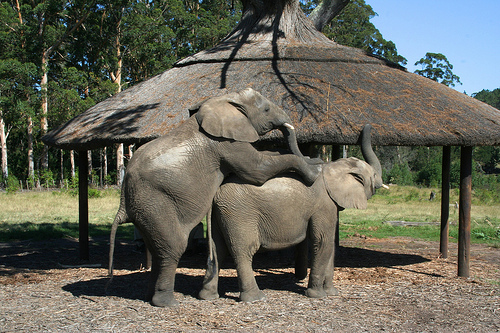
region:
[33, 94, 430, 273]
These are two elephants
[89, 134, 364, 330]
the elephants are large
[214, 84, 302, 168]
this is an ear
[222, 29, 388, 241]
this is a hut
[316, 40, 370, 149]
this is a roof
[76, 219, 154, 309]
this is a tail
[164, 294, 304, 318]
this is a foot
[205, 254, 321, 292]
this is a leg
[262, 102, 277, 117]
this is a tusk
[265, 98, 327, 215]
this is a trunk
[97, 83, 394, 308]
an elephant on top of other elephant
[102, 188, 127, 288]
long tail of elephant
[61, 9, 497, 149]
the roof of a shelter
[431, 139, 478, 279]
poles supporting a shelter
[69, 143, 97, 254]
pole supporting a shelter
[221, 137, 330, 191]
front leg on back of elephant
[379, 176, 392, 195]
white tusk of elephant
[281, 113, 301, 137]
white tusk of elephant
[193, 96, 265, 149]
long ear of elephant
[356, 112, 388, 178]
trunk of elephant is up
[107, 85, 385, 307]
Two elephants in a compound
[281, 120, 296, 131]
Elephant trunk made of ivory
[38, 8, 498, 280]
Man made shade hut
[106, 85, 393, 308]
Eelphant mounting another elephant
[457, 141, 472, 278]
Man made ground post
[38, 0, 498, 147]
Roof made from natural resources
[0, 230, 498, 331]
Mulch madefrom natural resources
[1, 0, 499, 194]
Wooded area outside the fence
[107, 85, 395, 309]
Elephant being mounted by another elephant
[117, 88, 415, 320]
Grey elephants are mating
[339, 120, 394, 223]
elephants trunk is in he air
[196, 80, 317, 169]
Elephant has tusks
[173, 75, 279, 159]
elephan has grey floppy ears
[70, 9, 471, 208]
covered shaded area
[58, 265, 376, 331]
there is bark on the ground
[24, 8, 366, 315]
there are trees behind the enclosure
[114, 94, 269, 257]
the male is on the back of the female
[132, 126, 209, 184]
the male has a grey patch on his back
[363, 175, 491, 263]
grass near the back on the enclosure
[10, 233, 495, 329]
ground covered with gray wood chips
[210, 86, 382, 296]
one elephant with front legs on other elephant's back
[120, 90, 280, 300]
elephant standing on rear legs in back of other elephant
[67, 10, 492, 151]
domed roof made of straw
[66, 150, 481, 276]
poles supporting outer edge of roof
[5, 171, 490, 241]
green and tan grass behind structure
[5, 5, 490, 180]
trees with white trunks growing behind grasses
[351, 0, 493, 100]
bright blue sky over trees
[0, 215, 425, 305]
large shadows on ground under roof and elephants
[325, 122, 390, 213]
elephant's head twisted to side